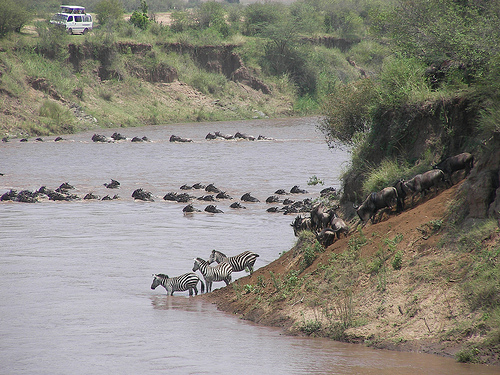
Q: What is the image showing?
A: It is showing a river.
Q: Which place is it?
A: It is a river.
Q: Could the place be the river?
A: Yes, it is the river.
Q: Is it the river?
A: Yes, it is the river.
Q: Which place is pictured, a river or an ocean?
A: It is a river.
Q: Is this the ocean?
A: No, it is the river.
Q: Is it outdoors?
A: Yes, it is outdoors.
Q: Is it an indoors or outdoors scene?
A: It is outdoors.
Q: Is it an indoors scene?
A: No, it is outdoors.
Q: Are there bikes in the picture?
A: No, there are no bikes.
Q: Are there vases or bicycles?
A: No, there are no bicycles or vases.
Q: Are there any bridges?
A: No, there are no bridges.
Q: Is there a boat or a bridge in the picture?
A: No, there are no bridges or boats.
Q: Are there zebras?
A: Yes, there is a zebra.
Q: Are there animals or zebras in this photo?
A: Yes, there is a zebra.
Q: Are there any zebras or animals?
A: Yes, there is a zebra.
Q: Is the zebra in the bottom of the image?
A: Yes, the zebra is in the bottom of the image.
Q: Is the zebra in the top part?
A: No, the zebra is in the bottom of the image.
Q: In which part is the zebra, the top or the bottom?
A: The zebra is in the bottom of the image.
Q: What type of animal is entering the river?
A: The animal is a zebra.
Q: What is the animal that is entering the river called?
A: The animal is a zebra.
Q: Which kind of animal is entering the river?
A: The animal is a zebra.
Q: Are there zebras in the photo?
A: Yes, there is a zebra.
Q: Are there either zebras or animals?
A: Yes, there is a zebra.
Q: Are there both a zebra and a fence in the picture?
A: No, there is a zebra but no fences.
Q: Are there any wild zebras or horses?
A: Yes, there is a wild zebra.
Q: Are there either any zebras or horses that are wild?
A: Yes, the zebra is wild.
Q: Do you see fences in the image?
A: No, there are no fences.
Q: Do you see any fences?
A: No, there are no fences.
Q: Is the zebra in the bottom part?
A: Yes, the zebra is in the bottom of the image.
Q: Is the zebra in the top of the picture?
A: No, the zebra is in the bottom of the image.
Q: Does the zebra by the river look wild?
A: Yes, the zebra is wild.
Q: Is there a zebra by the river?
A: Yes, there is a zebra by the river.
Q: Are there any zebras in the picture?
A: Yes, there is a zebra.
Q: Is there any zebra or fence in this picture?
A: Yes, there is a zebra.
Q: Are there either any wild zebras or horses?
A: Yes, there is a wild zebra.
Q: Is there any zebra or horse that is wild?
A: Yes, the zebra is wild.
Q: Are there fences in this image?
A: No, there are no fences.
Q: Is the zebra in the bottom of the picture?
A: Yes, the zebra is in the bottom of the image.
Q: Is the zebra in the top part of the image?
A: No, the zebra is in the bottom of the image.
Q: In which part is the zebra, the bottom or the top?
A: The zebra is in the bottom of the image.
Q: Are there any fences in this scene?
A: No, there are no fences.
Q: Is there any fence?
A: No, there are no fences.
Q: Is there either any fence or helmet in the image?
A: No, there are no fences or helmets.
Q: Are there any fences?
A: No, there are no fences.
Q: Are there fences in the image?
A: No, there are no fences.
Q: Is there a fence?
A: No, there are no fences.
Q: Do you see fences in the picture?
A: No, there are no fences.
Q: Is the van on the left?
A: Yes, the van is on the left of the image.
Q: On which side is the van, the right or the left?
A: The van is on the left of the image.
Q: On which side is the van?
A: The van is on the left of the image.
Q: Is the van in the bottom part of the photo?
A: No, the van is in the top of the image.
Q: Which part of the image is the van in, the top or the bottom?
A: The van is in the top of the image.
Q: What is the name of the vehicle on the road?
A: The vehicle is a van.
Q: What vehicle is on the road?
A: The vehicle is a van.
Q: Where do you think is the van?
A: The van is on the road.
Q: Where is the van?
A: The van is on the road.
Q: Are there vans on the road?
A: Yes, there is a van on the road.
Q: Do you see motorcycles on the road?
A: No, there is a van on the road.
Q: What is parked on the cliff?
A: The van is parked on the cliff.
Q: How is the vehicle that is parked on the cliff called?
A: The vehicle is a van.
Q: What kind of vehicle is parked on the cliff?
A: The vehicle is a van.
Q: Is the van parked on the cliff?
A: Yes, the van is parked on the cliff.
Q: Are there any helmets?
A: No, there are no helmets.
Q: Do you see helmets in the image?
A: No, there are no helmets.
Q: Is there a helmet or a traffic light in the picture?
A: No, there are no helmets or traffic lights.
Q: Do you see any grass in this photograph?
A: Yes, there is grass.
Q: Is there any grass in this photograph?
A: Yes, there is grass.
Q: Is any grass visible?
A: Yes, there is grass.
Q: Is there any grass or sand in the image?
A: Yes, there is grass.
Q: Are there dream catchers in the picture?
A: No, there are no dream catchers.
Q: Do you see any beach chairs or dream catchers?
A: No, there are no dream catchers or beach chairs.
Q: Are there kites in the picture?
A: No, there are no kites.